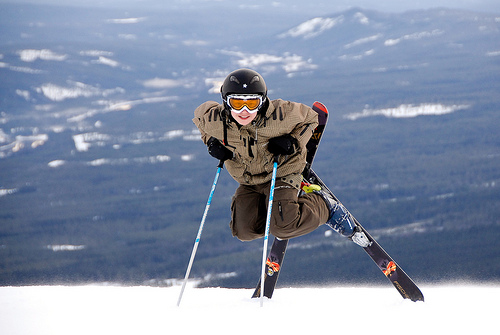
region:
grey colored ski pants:
[228, 173, 330, 252]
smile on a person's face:
[234, 113, 250, 121]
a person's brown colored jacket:
[188, 98, 317, 190]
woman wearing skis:
[161, 18, 381, 310]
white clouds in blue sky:
[12, 23, 39, 43]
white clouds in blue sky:
[155, 29, 183, 64]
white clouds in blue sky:
[280, 15, 322, 59]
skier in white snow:
[164, 57, 365, 326]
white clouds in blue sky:
[312, 13, 358, 57]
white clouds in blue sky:
[34, 39, 73, 74]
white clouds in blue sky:
[71, 65, 98, 107]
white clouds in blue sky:
[105, 10, 142, 44]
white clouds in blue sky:
[102, 57, 150, 99]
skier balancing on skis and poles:
[174, 69, 425, 302]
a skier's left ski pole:
[259, 158, 279, 300]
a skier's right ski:
[253, 100, 328, 298]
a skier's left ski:
[302, 166, 422, 303]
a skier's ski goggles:
[225, 95, 263, 111]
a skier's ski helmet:
[220, 70, 267, 93]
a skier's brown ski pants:
[231, 176, 330, 240]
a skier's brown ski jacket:
[192, 98, 317, 186]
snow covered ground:
[0, 285, 499, 333]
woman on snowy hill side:
[185, 59, 405, 323]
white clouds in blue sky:
[11, 19, 55, 63]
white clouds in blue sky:
[138, 13, 176, 54]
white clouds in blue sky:
[314, 22, 339, 56]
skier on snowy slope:
[184, 75, 355, 305]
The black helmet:
[209, 69, 265, 100]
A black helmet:
[212, 67, 266, 99]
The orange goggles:
[221, 92, 270, 110]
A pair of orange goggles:
[220, 91, 269, 107]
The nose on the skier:
[235, 105, 250, 117]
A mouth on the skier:
[236, 110, 258, 124]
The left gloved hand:
[198, 133, 238, 167]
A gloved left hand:
[203, 137, 237, 167]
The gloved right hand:
[259, 130, 310, 170]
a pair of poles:
[154, 137, 290, 318]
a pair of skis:
[232, 72, 439, 317]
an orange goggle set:
[221, 85, 263, 119]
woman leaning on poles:
[142, 62, 434, 311]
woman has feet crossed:
[196, 104, 425, 311]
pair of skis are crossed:
[226, 94, 450, 313]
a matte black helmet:
[203, 61, 282, 119]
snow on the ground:
[19, 268, 498, 333]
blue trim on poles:
[189, 145, 289, 214]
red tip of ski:
[310, 91, 345, 128]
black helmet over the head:
[217, 73, 269, 125]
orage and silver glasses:
[224, 93, 268, 110]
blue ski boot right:
[305, 160, 367, 242]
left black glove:
[200, 133, 238, 158]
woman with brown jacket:
[211, 91, 296, 188]